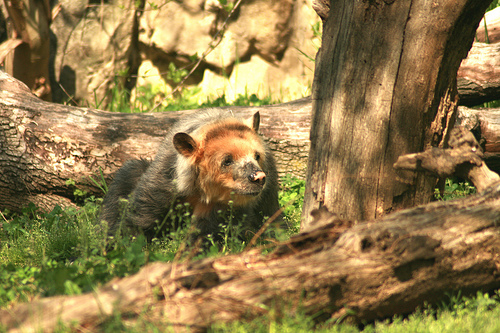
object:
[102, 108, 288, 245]
animal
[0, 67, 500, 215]
log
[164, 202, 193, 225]
flowers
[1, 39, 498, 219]
trunk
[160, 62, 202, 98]
vine leaves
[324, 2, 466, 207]
tree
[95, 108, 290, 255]
bear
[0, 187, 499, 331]
log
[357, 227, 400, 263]
holes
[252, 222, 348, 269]
openings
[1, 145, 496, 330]
tree trunk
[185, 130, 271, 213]
head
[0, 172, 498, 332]
grass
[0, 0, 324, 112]
wall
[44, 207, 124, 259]
leaves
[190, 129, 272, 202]
face